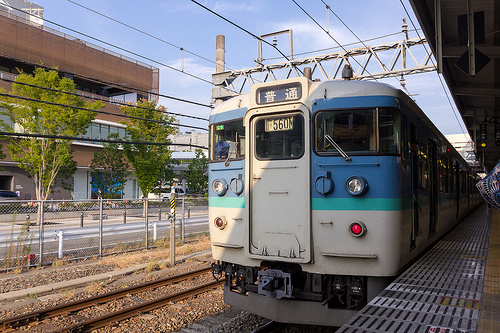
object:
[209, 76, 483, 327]
train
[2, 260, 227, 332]
tracks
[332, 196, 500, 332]
platform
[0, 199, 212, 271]
fence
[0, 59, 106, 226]
tree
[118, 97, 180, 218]
tree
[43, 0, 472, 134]
sky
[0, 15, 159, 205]
building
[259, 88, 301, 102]
sign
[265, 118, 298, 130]
number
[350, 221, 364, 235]
light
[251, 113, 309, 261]
door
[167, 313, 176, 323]
rocks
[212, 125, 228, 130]
window sticker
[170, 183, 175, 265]
post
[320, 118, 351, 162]
windshield wiper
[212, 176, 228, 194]
lights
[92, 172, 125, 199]
window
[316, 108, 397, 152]
windshield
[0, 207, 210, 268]
sidewalk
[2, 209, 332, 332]
ground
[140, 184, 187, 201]
van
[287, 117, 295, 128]
letter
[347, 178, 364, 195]
light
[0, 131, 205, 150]
cables